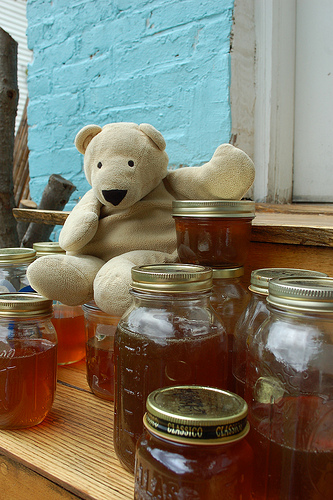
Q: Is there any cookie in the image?
A: No, there are no cookies.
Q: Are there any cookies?
A: No, there are no cookies.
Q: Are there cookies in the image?
A: No, there are no cookies.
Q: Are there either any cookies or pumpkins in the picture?
A: No, there are no cookies or pumpkins.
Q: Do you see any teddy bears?
A: Yes, there is a teddy bear.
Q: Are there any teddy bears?
A: Yes, there is a teddy bear.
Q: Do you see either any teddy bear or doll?
A: Yes, there is a teddy bear.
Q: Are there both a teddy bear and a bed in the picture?
A: No, there is a teddy bear but no beds.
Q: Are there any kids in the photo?
A: No, there are no kids.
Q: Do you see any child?
A: No, there are no children.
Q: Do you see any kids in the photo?
A: No, there are no kids.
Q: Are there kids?
A: No, there are no kids.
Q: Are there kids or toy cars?
A: No, there are no kids or toy cars.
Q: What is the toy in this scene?
A: The toy is a teddy bear.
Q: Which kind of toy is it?
A: The toy is a teddy bear.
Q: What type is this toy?
A: This is a teddy bear.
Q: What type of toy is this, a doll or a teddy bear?
A: This is a teddy bear.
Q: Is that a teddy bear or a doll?
A: That is a teddy bear.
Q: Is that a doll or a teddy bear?
A: That is a teddy bear.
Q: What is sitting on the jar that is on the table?
A: The teddy bear is sitting on the jar.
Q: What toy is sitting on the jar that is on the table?
A: The toy is a teddy bear.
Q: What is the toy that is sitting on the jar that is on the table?
A: The toy is a teddy bear.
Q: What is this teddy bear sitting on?
A: The teddy bear is sitting on the jar.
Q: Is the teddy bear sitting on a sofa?
A: No, the teddy bear is sitting on the jar.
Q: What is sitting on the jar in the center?
A: The teddy bear is sitting on the jar.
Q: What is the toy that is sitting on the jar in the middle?
A: The toy is a teddy bear.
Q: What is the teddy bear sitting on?
A: The teddy bear is sitting on the jar.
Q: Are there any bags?
A: No, there are no bags.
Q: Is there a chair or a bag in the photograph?
A: No, there are no bags or chairs.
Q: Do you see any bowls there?
A: No, there are no bowls.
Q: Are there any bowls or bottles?
A: No, there are no bowls or bottles.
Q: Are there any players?
A: No, there are no players.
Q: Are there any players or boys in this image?
A: No, there are no players or boys.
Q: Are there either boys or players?
A: No, there are no players or boys.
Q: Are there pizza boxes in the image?
A: No, there are no pizza boxes.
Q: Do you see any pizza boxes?
A: No, there are no pizza boxes.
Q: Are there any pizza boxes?
A: No, there are no pizza boxes.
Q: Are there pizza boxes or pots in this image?
A: No, there are no pizza boxes or pots.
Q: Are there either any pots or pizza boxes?
A: No, there are no pizza boxes or pots.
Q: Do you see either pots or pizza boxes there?
A: No, there are no pizza boxes or pots.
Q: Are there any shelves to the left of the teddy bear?
A: No, there is a jar to the left of the teddy bear.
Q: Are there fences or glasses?
A: No, there are no fences or glasses.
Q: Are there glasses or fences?
A: No, there are no fences or glasses.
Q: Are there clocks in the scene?
A: No, there are no clocks.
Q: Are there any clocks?
A: No, there are no clocks.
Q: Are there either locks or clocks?
A: No, there are no clocks or locks.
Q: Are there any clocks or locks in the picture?
A: No, there are no clocks or locks.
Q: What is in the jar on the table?
A: The liquid is in the jar.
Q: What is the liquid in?
A: The liquid is in the jar.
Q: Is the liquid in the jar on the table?
A: Yes, the liquid is in the jar.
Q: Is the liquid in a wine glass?
A: No, the liquid is in the jar.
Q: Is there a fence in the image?
A: No, there are no fences.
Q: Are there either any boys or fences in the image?
A: No, there are no fences or boys.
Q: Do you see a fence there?
A: No, there are no fences.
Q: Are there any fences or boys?
A: No, there are no fences or boys.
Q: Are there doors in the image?
A: Yes, there is a door.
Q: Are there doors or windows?
A: Yes, there is a door.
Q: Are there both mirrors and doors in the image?
A: No, there is a door but no mirrors.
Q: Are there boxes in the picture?
A: No, there are no boxes.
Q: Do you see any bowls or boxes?
A: No, there are no boxes or bowls.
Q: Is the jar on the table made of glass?
A: Yes, the jar is made of glass.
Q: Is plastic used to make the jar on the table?
A: No, the jar is made of glass.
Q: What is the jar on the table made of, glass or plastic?
A: The jar is made of glass.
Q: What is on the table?
A: The jar is on the table.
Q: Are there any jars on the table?
A: Yes, there is a jar on the table.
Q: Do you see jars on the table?
A: Yes, there is a jar on the table.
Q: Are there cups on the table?
A: No, there is a jar on the table.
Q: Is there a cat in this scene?
A: No, there are no cats.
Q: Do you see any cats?
A: No, there are no cats.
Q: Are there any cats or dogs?
A: No, there are no cats or dogs.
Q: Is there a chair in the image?
A: No, there are no chairs.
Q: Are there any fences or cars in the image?
A: No, there are no cars or fences.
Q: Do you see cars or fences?
A: No, there are no cars or fences.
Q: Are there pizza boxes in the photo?
A: No, there are no pizza boxes.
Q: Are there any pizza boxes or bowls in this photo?
A: No, there are no pizza boxes or bowls.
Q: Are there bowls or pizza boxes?
A: No, there are no pizza boxes or bowls.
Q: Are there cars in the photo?
A: No, there are no cars.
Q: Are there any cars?
A: No, there are no cars.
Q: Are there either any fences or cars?
A: No, there are no cars or fences.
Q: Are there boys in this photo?
A: No, there are no boys.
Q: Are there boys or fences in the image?
A: No, there are no boys or fences.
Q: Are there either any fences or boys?
A: No, there are no boys or fences.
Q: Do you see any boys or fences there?
A: No, there are no boys or fences.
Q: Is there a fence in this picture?
A: No, there are no fences.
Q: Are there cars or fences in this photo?
A: No, there are no fences or cars.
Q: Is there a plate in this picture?
A: No, there are no plates.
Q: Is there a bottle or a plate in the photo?
A: No, there are no plates or bottles.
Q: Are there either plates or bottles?
A: No, there are no plates or bottles.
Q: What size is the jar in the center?
A: The jar is small.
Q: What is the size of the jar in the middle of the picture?
A: The jar is small.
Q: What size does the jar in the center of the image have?
A: The jar has small size.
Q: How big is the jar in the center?
A: The jar is small.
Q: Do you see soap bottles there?
A: No, there are no soap bottles.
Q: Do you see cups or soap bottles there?
A: No, there are no soap bottles or cups.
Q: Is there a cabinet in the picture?
A: No, there are no cabinets.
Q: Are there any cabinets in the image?
A: No, there are no cabinets.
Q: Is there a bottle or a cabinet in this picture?
A: No, there are no cabinets or bottles.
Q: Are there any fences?
A: No, there are no fences.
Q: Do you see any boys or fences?
A: No, there are no fences or boys.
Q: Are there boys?
A: No, there are no boys.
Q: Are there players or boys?
A: No, there are no boys or players.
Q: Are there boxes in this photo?
A: No, there are no boxes.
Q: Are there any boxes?
A: No, there are no boxes.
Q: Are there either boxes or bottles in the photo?
A: No, there are no boxes or bottles.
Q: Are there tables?
A: Yes, there is a table.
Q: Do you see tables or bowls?
A: Yes, there is a table.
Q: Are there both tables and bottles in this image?
A: No, there is a table but no bottles.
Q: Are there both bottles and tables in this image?
A: No, there is a table but no bottles.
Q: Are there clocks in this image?
A: No, there are no clocks.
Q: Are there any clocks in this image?
A: No, there are no clocks.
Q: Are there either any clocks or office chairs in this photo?
A: No, there are no clocks or office chairs.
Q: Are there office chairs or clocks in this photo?
A: No, there are no clocks or office chairs.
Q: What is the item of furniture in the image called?
A: The piece of furniture is a table.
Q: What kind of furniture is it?
A: The piece of furniture is a table.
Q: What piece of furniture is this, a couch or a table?
A: This is a table.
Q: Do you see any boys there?
A: No, there are no boys.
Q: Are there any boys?
A: No, there are no boys.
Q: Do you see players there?
A: No, there are no players.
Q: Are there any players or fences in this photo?
A: No, there are no players or fences.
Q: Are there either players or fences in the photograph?
A: No, there are no fences or players.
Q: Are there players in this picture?
A: No, there are no players.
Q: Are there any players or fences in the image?
A: No, there are no players or fences.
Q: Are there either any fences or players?
A: No, there are no players or fences.